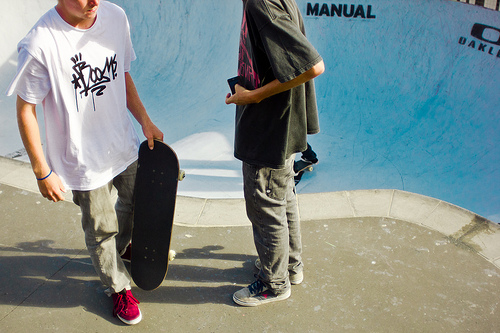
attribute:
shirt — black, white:
[16, 8, 328, 203]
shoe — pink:
[96, 278, 152, 333]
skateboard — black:
[130, 143, 187, 310]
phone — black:
[212, 66, 269, 124]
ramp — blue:
[319, 6, 477, 215]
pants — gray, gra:
[61, 149, 331, 313]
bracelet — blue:
[23, 162, 75, 200]